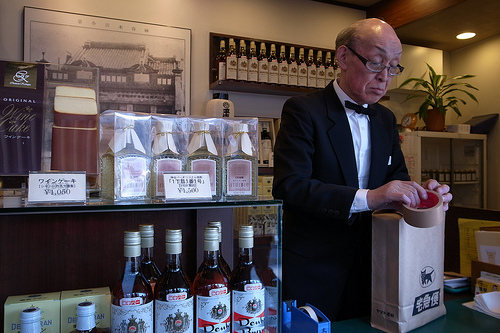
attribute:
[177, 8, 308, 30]
wall — white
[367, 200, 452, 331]
bag — brown, paper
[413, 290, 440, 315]
design — black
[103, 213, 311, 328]
bottles — wine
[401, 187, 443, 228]
tape — rolled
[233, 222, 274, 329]
bottle — one, wine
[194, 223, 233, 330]
bottle — wine, one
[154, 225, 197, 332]
bottle — wine, one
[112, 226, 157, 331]
bottle — wine, one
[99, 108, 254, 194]
bottle — wine, one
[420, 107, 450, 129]
flower pot — brown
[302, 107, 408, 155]
black tuxedo — black 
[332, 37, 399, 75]
glasses — black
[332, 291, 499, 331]
countertop — green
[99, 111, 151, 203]
liquor — some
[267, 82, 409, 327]
tuxedo — black 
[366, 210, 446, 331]
paper bag — brown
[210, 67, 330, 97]
shelf — wooden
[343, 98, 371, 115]
bow tie — one, black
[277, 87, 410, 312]
suit — black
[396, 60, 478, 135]
plant — green 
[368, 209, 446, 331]
paper package — brown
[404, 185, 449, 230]
packing tape — rolled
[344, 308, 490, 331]
countertop — one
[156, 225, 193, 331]
bottle — one, wine, shelved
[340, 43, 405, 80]
frame — black